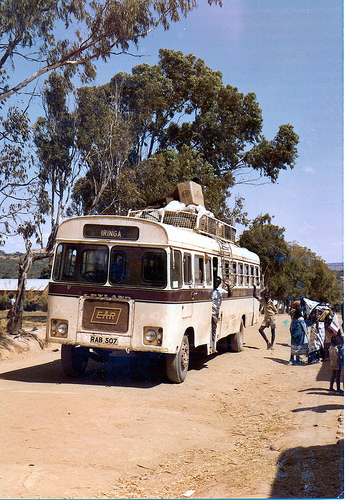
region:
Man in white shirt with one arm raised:
[208, 273, 231, 355]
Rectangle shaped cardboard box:
[175, 180, 205, 206]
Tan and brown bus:
[39, 207, 264, 384]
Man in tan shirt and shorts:
[249, 278, 280, 351]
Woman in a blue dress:
[287, 307, 311, 363]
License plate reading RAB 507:
[84, 335, 118, 344]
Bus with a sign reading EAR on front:
[42, 212, 267, 385]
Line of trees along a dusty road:
[5, 5, 343, 495]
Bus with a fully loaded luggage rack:
[43, 182, 264, 383]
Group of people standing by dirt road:
[5, 293, 339, 498]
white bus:
[53, 205, 248, 357]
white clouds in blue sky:
[222, 11, 253, 48]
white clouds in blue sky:
[276, 51, 299, 80]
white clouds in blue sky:
[265, 174, 309, 207]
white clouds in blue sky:
[259, 66, 302, 94]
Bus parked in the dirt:
[42, 198, 268, 384]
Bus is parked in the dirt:
[33, 183, 269, 383]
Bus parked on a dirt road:
[41, 187, 269, 384]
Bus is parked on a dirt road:
[31, 186, 269, 379]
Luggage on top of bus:
[121, 170, 249, 239]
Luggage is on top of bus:
[129, 179, 238, 235]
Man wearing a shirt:
[206, 286, 227, 316]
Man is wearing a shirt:
[209, 284, 229, 315]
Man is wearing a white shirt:
[209, 285, 228, 316]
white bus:
[57, 212, 265, 373]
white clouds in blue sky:
[280, 200, 299, 211]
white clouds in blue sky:
[239, 187, 268, 199]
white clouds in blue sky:
[316, 63, 341, 81]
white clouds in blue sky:
[230, 32, 268, 82]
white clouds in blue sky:
[287, 32, 312, 64]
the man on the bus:
[209, 276, 230, 353]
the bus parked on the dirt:
[46, 180, 261, 383]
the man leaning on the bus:
[252, 284, 276, 349]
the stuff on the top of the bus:
[127, 180, 237, 244]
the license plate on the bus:
[89, 336, 117, 344]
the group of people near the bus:
[289, 295, 344, 392]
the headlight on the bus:
[145, 329, 156, 340]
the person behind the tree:
[6, 292, 14, 318]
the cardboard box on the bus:
[177, 181, 203, 207]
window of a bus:
[51, 245, 105, 283]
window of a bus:
[106, 246, 163, 287]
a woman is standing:
[289, 306, 311, 364]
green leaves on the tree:
[154, 157, 179, 181]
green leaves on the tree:
[308, 258, 324, 276]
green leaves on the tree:
[259, 253, 291, 297]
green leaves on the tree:
[37, 182, 60, 212]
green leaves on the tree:
[28, 157, 74, 196]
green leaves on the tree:
[68, 106, 127, 163]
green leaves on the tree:
[206, 111, 257, 140]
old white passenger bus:
[49, 199, 268, 377]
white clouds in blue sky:
[199, 24, 233, 47]